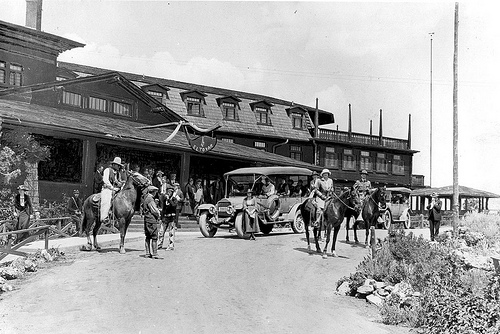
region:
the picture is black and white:
[0, 20, 493, 320]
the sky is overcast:
[112, 0, 472, 168]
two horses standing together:
[277, 158, 403, 245]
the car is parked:
[197, 133, 326, 238]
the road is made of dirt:
[134, 234, 331, 330]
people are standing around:
[70, 140, 230, 212]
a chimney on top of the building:
[15, 2, 53, 34]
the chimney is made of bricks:
[17, 2, 49, 29]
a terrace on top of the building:
[300, 90, 418, 160]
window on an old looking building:
[185, 97, 205, 119]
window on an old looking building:
[109, 100, 139, 116]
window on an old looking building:
[85, 95, 111, 112]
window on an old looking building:
[57, 88, 87, 108]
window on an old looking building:
[186, 102, 201, 117]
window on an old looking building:
[320, 146, 337, 170]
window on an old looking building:
[372, 153, 387, 176]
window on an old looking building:
[389, 156, 404, 176]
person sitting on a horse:
[73, 153, 155, 252]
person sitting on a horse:
[292, 167, 369, 264]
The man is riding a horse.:
[77, 148, 154, 259]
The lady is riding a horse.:
[299, 165, 361, 266]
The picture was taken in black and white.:
[3, 2, 498, 330]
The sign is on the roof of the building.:
[138, 106, 242, 166]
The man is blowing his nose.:
[423, 185, 455, 239]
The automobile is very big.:
[195, 153, 322, 245]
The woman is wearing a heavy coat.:
[2, 165, 41, 240]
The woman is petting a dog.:
[2, 166, 34, 241]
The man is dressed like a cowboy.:
[92, 146, 131, 227]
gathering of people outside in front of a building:
[33, 27, 471, 263]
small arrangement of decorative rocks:
[350, 274, 393, 311]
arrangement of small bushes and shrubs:
[368, 220, 491, 326]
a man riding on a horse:
[77, 148, 146, 259]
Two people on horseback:
[297, 143, 394, 261]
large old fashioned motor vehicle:
[195, 150, 317, 235]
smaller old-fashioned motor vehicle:
[366, 182, 425, 228]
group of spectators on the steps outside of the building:
[178, 169, 213, 226]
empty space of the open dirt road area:
[104, 259, 354, 331]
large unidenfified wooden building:
[11, 12, 440, 188]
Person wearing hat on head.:
[317, 163, 332, 175]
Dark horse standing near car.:
[297, 203, 359, 269]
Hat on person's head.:
[358, 163, 379, 187]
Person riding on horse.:
[343, 168, 403, 235]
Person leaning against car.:
[234, 173, 266, 264]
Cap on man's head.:
[145, 180, 163, 197]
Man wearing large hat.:
[110, 155, 128, 169]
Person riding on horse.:
[74, 162, 141, 232]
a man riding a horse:
[77, 156, 153, 253]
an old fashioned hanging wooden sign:
[143, 118, 225, 156]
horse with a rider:
[62, 149, 152, 259]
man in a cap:
[135, 176, 167, 263]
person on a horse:
[290, 164, 360, 262]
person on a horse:
[344, 163, 389, 248]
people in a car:
[197, 147, 332, 247]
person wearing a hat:
[238, 182, 261, 244]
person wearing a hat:
[89, 150, 129, 227]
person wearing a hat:
[353, 161, 375, 213]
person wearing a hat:
[307, 163, 342, 220]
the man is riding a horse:
[98, 154, 121, 219]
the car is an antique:
[197, 156, 314, 242]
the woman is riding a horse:
[295, 167, 363, 259]